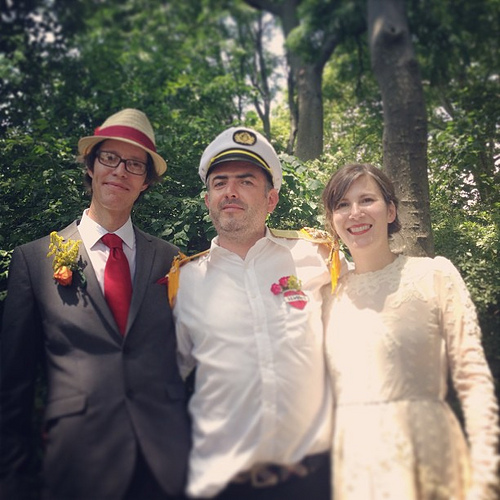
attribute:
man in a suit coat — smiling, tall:
[9, 109, 187, 497]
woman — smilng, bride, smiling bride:
[321, 165, 497, 500]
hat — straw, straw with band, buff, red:
[76, 104, 177, 173]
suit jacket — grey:
[4, 225, 182, 493]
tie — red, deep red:
[103, 237, 128, 326]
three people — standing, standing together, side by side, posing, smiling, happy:
[0, 109, 499, 496]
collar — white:
[82, 216, 135, 250]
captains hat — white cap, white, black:
[196, 127, 291, 194]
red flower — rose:
[52, 265, 73, 288]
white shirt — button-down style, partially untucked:
[179, 232, 329, 478]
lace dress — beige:
[327, 260, 499, 495]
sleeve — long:
[435, 254, 499, 497]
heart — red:
[288, 284, 311, 312]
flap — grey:
[45, 399, 91, 424]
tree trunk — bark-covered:
[373, 1, 430, 257]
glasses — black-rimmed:
[98, 150, 148, 179]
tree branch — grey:
[250, 1, 308, 42]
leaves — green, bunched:
[81, 0, 259, 105]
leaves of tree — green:
[46, 19, 234, 106]